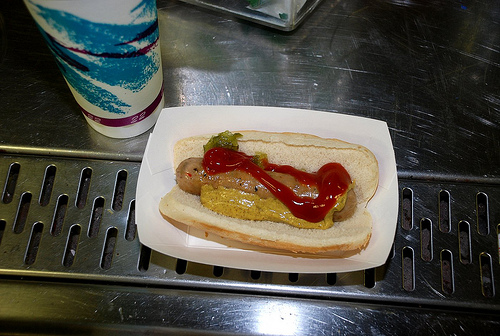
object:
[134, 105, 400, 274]
carton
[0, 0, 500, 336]
counter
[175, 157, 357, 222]
hotdog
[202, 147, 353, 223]
ketchup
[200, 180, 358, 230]
mustard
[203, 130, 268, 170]
relish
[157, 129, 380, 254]
bun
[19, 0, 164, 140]
cup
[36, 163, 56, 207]
hole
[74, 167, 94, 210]
hole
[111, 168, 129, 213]
hole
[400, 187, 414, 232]
hole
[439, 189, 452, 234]
hole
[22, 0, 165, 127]
design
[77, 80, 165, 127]
stripe